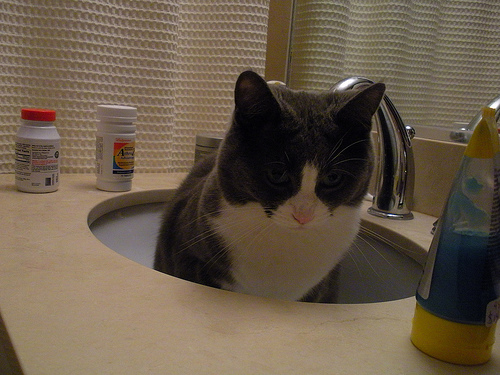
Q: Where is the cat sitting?
A: In a sink.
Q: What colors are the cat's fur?
A: White and grey.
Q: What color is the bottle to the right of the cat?
A: Yellow.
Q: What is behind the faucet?
A: Mirror.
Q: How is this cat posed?
A: Sitting.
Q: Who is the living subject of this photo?
A: The cat.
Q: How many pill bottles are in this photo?
A: Two.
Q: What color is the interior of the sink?
A: White.